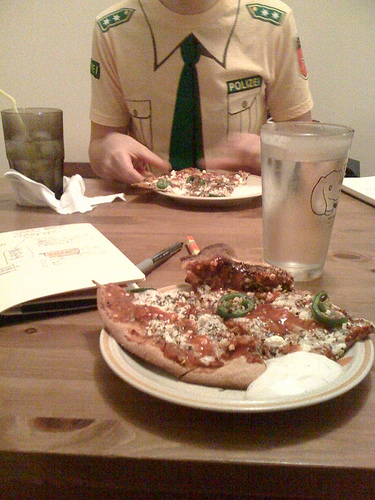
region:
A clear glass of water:
[260, 109, 351, 292]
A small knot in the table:
[333, 246, 366, 265]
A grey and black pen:
[132, 236, 181, 287]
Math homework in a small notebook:
[5, 225, 96, 289]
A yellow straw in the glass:
[0, 90, 40, 148]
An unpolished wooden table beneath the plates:
[18, 354, 100, 447]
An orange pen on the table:
[183, 226, 214, 261]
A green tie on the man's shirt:
[157, 36, 217, 166]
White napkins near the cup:
[7, 160, 122, 216]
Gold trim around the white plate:
[134, 379, 250, 418]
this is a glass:
[259, 119, 345, 247]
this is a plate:
[205, 393, 260, 417]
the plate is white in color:
[189, 389, 209, 404]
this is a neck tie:
[175, 68, 207, 134]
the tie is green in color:
[174, 103, 199, 137]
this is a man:
[82, 26, 289, 138]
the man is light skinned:
[100, 141, 132, 172]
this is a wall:
[31, 54, 72, 75]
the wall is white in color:
[16, 27, 54, 75]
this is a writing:
[226, 81, 259, 90]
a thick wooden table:
[1, 174, 373, 497]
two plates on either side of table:
[95, 162, 374, 411]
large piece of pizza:
[95, 275, 370, 384]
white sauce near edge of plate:
[238, 351, 373, 406]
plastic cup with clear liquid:
[258, 120, 353, 279]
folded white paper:
[0, 222, 146, 318]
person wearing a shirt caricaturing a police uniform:
[86, 0, 315, 205]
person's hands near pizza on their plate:
[103, 128, 293, 201]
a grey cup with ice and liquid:
[4, 108, 64, 195]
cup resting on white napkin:
[0, 104, 125, 213]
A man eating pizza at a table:
[2, 62, 364, 428]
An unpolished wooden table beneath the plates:
[0, 316, 124, 465]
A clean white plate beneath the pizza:
[104, 361, 236, 415]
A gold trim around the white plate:
[122, 377, 183, 400]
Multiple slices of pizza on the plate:
[118, 262, 359, 376]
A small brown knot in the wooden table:
[335, 247, 367, 267]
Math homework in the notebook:
[4, 225, 133, 297]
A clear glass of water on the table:
[260, 117, 351, 282]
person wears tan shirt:
[103, 10, 284, 153]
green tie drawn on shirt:
[159, 35, 237, 196]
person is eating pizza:
[148, 150, 250, 212]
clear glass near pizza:
[261, 110, 349, 297]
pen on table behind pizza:
[137, 221, 191, 295]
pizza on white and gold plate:
[151, 270, 336, 415]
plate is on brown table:
[92, 273, 369, 441]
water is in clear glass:
[252, 115, 323, 277]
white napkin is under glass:
[23, 170, 122, 225]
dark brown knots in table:
[43, 392, 121, 468]